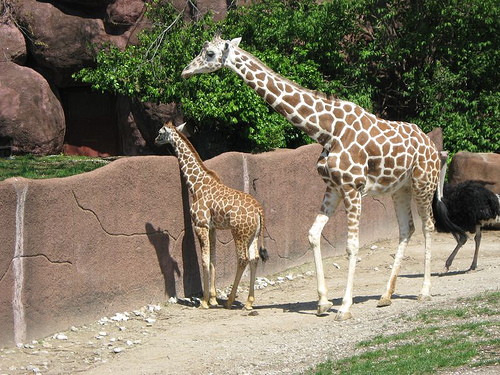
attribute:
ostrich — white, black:
[438, 147, 500, 274]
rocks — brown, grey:
[4, 2, 183, 146]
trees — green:
[73, 2, 499, 146]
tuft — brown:
[439, 202, 464, 246]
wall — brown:
[3, 5, 222, 152]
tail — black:
[257, 210, 274, 261]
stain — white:
[13, 179, 38, 343]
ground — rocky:
[7, 236, 490, 375]